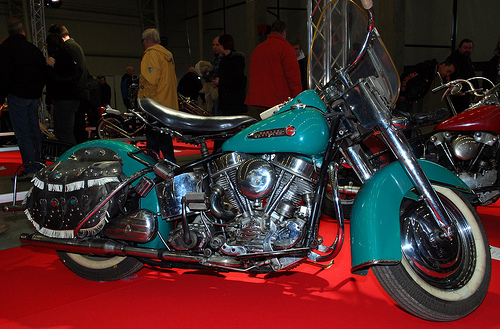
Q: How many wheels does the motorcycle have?
A: 2.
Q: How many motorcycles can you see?
A: 3.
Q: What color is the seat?
A: Black.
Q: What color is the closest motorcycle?
A: Blue.